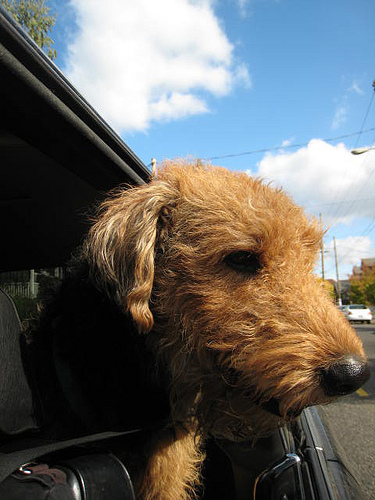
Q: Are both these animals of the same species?
A: Yes, all the animals are dogs.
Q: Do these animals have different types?
A: No, all the animals are dogs.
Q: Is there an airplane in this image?
A: No, there are no airplanes.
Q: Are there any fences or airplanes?
A: No, there are no airplanes or fences.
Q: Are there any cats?
A: No, there are no cats.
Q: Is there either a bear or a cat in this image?
A: No, there are no cats or bears.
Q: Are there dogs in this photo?
A: Yes, there is a dog.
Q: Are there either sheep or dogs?
A: Yes, there is a dog.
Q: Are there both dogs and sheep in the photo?
A: No, there is a dog but no sheep.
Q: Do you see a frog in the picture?
A: No, there are no frogs.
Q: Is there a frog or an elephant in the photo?
A: No, there are no frogs or elephants.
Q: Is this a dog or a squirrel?
A: This is a dog.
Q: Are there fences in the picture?
A: No, there are no fences.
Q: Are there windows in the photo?
A: Yes, there is a window.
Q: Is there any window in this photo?
A: Yes, there is a window.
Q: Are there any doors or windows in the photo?
A: Yes, there is a window.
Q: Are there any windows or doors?
A: Yes, there is a window.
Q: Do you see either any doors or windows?
A: Yes, there is a window.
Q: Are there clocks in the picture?
A: No, there are no clocks.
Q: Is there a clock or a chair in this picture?
A: No, there are no clocks or chairs.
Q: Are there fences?
A: No, there are no fences.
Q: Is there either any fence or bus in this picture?
A: No, there are no fences or buses.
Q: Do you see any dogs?
A: Yes, there is a dog.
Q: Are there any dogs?
A: Yes, there is a dog.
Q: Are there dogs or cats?
A: Yes, there is a dog.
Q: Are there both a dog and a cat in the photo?
A: No, there is a dog but no cats.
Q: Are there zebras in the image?
A: No, there are no zebras.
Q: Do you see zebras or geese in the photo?
A: No, there are no zebras or geese.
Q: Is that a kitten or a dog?
A: That is a dog.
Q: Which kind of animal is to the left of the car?
A: The animal is a dog.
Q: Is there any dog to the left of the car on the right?
A: Yes, there is a dog to the left of the car.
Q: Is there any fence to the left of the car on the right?
A: No, there is a dog to the left of the car.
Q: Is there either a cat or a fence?
A: No, there are no cats or fences.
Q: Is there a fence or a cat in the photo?
A: No, there are no cats or fences.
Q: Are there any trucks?
A: No, there are no trucks.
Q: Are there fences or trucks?
A: No, there are no trucks or fences.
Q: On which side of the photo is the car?
A: The car is on the right of the image.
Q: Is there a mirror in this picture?
A: No, there are no mirrors.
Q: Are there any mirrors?
A: No, there are no mirrors.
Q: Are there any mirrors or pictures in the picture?
A: No, there are no mirrors or pictures.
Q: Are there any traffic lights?
A: No, there are no traffic lights.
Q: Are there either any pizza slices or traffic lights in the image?
A: No, there are no traffic lights or pizza slices.